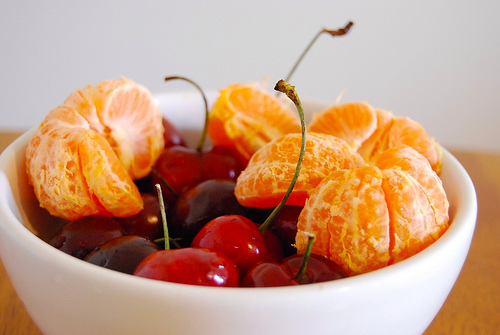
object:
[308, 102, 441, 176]
orange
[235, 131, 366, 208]
orange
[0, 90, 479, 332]
bowl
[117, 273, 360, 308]
edge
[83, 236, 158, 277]
cherries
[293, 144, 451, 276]
oranges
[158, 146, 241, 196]
cherries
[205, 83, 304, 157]
oranges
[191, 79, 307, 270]
cherry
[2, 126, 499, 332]
table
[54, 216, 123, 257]
cherries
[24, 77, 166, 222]
oranges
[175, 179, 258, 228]
cherries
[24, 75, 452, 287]
fruit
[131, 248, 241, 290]
cherries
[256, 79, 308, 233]
stem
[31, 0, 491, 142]
wall